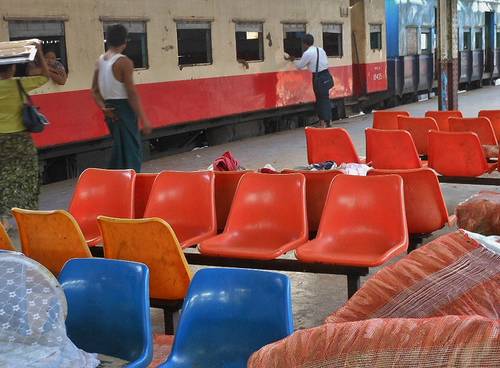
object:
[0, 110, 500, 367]
area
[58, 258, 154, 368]
chair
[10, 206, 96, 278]
chair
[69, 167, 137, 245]
chair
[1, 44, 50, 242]
woman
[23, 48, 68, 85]
person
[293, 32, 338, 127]
woman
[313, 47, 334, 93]
pocketbook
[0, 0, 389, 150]
train car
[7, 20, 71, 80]
window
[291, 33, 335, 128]
man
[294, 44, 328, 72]
shirt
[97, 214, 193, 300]
seat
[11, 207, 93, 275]
seat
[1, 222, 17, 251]
seat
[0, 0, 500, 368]
train station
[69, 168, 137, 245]
seat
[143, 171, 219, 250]
seat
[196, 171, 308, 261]
seat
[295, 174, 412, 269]
seat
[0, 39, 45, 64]
something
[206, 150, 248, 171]
pile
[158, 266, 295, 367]
seat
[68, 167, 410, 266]
four seats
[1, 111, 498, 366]
waiting area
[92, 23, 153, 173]
man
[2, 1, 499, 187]
train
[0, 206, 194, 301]
three seats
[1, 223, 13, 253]
chair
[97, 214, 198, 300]
chair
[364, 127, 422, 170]
chair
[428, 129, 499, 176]
chair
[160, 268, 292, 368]
chair